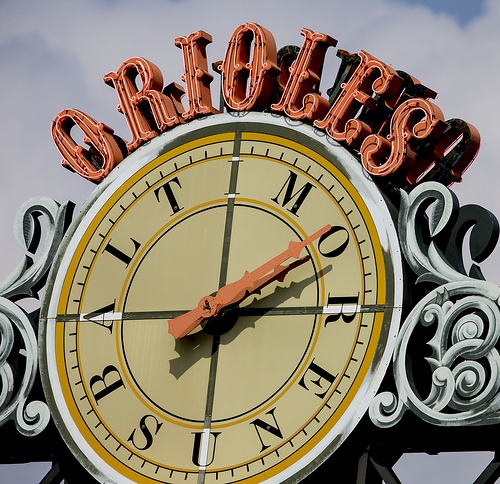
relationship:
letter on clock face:
[270, 167, 320, 215] [51, 125, 385, 482]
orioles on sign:
[49, 23, 447, 181] [21, 13, 470, 257]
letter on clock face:
[144, 172, 184, 221] [51, 125, 385, 482]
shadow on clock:
[157, 264, 346, 382] [41, 55, 493, 482]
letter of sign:
[356, 97, 442, 179] [33, 11, 447, 200]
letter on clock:
[270, 167, 320, 215] [27, 102, 407, 478]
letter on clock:
[144, 172, 184, 221] [72, 120, 430, 481]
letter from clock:
[97, 230, 144, 269] [27, 102, 407, 478]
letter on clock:
[86, 360, 126, 405] [50, 116, 382, 481]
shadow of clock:
[157, 264, 346, 382] [65, 94, 399, 468]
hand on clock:
[170, 222, 337, 338] [27, 102, 407, 478]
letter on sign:
[173, 30, 218, 120] [50, 20, 480, 193]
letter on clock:
[247, 405, 294, 466] [50, 116, 382, 481]